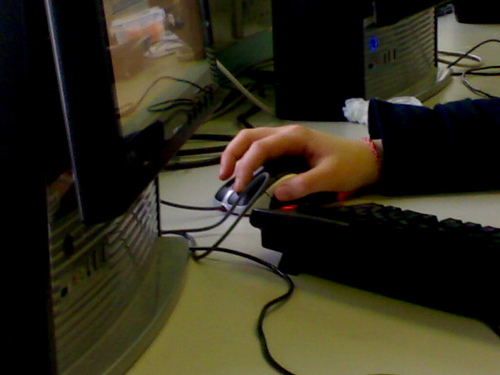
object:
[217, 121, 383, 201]
hand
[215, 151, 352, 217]
mouse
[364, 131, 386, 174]
bracelet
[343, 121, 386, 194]
wrist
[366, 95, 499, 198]
sleeve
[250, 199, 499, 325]
keyboard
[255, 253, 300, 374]
cord